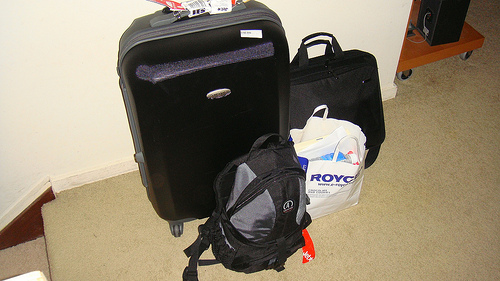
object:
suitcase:
[116, 0, 291, 238]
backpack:
[180, 133, 312, 281]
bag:
[289, 32, 386, 170]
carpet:
[305, 1, 499, 280]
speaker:
[413, 0, 470, 46]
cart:
[393, 0, 485, 81]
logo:
[282, 199, 295, 213]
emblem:
[206, 88, 231, 100]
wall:
[0, 1, 137, 229]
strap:
[247, 133, 287, 160]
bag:
[289, 104, 370, 220]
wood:
[0, 187, 55, 249]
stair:
[0, 198, 56, 280]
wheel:
[397, 69, 413, 81]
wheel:
[460, 50, 473, 61]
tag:
[300, 228, 315, 264]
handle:
[291, 31, 344, 67]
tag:
[181, 0, 208, 17]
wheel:
[169, 220, 184, 237]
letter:
[311, 173, 356, 183]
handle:
[310, 104, 329, 119]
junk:
[305, 150, 357, 165]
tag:
[150, 0, 184, 11]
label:
[239, 29, 263, 39]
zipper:
[328, 69, 339, 80]